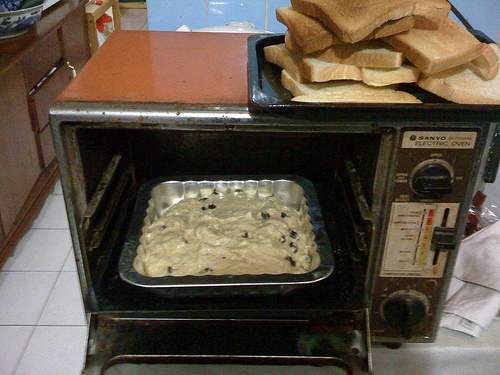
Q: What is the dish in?
A: An oven.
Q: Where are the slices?
A: In a pile.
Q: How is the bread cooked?
A: Toasted.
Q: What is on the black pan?
A: Toasted bread.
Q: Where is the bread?
A: In a pan.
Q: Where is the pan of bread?
A: On top of the microwave.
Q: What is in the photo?
A: Food in a pan.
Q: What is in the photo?
A: An oven.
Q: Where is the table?
A: Below the oven.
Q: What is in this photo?
A: A toaster oven.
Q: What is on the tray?
A: White toast.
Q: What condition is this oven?
A: Very bad.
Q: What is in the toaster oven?
A: A tray of food.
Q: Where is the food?
A: In the oven.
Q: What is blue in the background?
A: Blue tile backsplash.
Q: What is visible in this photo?
A: An oven.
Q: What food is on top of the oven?
A: Bread.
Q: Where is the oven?
A: Kitchen.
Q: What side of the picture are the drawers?
A: Left side.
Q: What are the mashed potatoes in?
A: Pan.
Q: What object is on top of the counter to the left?
A: A bowl.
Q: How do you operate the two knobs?
A: Turn them.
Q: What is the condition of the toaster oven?
A: Old and dirty.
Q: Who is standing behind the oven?
A: No one.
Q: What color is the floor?
A: White.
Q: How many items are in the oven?
A: One.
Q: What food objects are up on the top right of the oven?
A: Toast.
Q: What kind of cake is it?
A: Chocolate chip.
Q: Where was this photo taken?
A: In a kitchen.